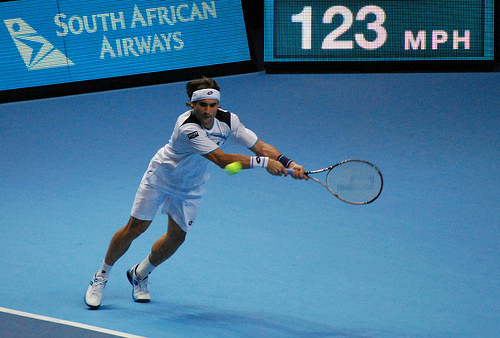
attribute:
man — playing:
[86, 77, 309, 307]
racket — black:
[284, 159, 383, 206]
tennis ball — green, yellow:
[226, 161, 242, 174]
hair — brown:
[184, 76, 219, 105]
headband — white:
[191, 88, 222, 101]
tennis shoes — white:
[125, 265, 151, 303]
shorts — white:
[129, 184, 200, 232]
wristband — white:
[251, 155, 269, 168]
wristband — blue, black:
[278, 154, 292, 172]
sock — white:
[137, 258, 156, 278]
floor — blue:
[1, 68, 499, 335]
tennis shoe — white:
[84, 274, 107, 310]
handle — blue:
[284, 168, 294, 178]